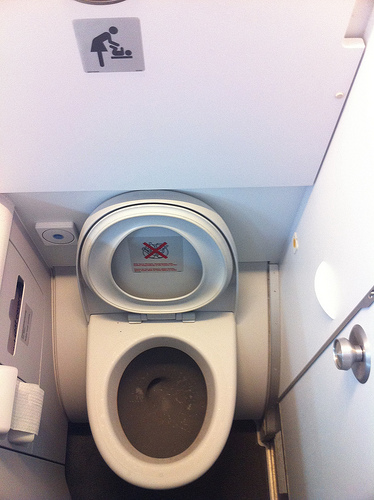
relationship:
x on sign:
[141, 242, 168, 260] [128, 237, 185, 275]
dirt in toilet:
[135, 370, 195, 436] [76, 190, 239, 489]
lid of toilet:
[74, 187, 240, 326] [76, 190, 239, 489]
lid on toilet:
[75, 190, 241, 323] [76, 190, 239, 489]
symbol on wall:
[72, 16, 147, 73] [0, 0, 373, 268]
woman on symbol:
[89, 26, 120, 66] [72, 16, 147, 73]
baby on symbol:
[109, 45, 132, 59] [72, 16, 147, 73]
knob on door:
[332, 324, 370, 383] [262, 287, 373, 499]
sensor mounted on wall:
[34, 221, 79, 249] [0, 0, 373, 268]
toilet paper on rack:
[14, 381, 44, 434] [1, 363, 44, 444]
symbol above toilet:
[72, 16, 147, 73] [76, 190, 239, 489]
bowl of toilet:
[117, 347, 208, 457] [76, 190, 239, 489]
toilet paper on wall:
[14, 381, 44, 434] [0, 195, 75, 499]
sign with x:
[128, 237, 185, 275] [141, 242, 168, 260]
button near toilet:
[289, 233, 299, 254] [76, 190, 239, 489]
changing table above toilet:
[1, 0, 366, 195] [76, 190, 239, 489]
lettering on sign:
[132, 261, 179, 274] [128, 237, 185, 275]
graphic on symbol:
[91, 25, 133, 65] [72, 16, 147, 73]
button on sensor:
[53, 232, 65, 241] [34, 221, 79, 249]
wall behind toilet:
[0, 0, 373, 268] [76, 190, 239, 489]